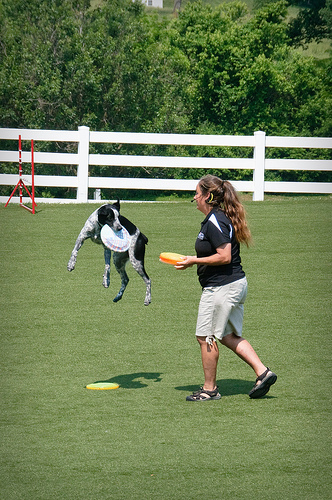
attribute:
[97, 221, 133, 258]
frisbee — round, small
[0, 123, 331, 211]
fence — short, white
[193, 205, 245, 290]
shirt — black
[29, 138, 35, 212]
pole — red, metal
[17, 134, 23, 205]
pole — red, metal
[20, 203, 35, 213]
pole — red, metal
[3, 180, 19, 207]
pole — red, metal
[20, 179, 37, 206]
pole — red, metal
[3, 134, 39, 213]
obstacle course — red, metal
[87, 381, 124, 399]
frisbee — green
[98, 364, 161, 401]
shadow — woman 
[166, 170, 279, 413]
woman — white  , black   , standing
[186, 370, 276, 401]
feet — woman's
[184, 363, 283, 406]
sandals — brown camp 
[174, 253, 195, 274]
hands — woman's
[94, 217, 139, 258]
frisbee — mid-flight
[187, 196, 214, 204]
microphone — face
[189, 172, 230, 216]
head — woman's  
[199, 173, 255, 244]
hair — long, brown 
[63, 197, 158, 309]
dog — black, white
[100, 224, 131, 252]
frisbee — blue 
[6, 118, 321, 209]
fence — red metal barricade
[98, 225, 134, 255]
frisbee — white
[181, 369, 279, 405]
sneakers — black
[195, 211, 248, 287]
shirt — white polo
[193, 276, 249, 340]
shorts — tan khaki cotton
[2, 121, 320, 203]
fence — white wood picket, white, wooden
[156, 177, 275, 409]
trainer — dog 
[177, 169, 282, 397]
trainer — dog 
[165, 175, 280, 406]
trainer — dog 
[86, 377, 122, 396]
frisbee — yellow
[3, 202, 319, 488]
grass — yellow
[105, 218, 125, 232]
mouth — dog's 